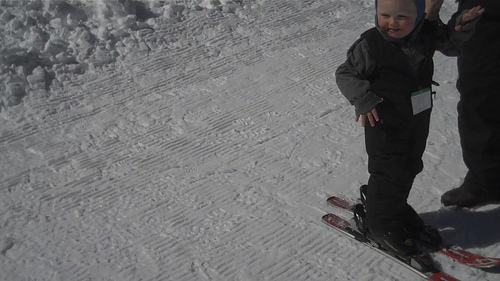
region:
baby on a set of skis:
[311, 171, 463, 272]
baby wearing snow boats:
[353, 189, 440, 264]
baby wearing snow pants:
[358, 107, 415, 232]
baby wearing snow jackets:
[298, 19, 452, 157]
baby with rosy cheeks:
[373, 15, 413, 37]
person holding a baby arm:
[425, 0, 476, 75]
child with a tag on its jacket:
[403, 83, 438, 118]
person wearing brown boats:
[429, 168, 492, 218]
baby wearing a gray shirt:
[328, 41, 374, 119]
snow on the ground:
[83, 56, 169, 194]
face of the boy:
[362, 3, 442, 49]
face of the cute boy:
[365, 4, 432, 59]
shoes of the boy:
[336, 169, 441, 256]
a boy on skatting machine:
[307, 158, 471, 279]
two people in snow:
[328, 59, 496, 200]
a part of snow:
[14, 3, 200, 56]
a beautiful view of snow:
[33, 35, 495, 253]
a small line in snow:
[284, 79, 356, 134]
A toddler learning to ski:
[320, 0, 499, 277]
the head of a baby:
[347, 0, 447, 62]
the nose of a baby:
[381, 18, 407, 48]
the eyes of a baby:
[371, 9, 424, 25]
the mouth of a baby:
[378, 21, 410, 44]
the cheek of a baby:
[368, 7, 395, 38]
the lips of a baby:
[373, 22, 414, 42]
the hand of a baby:
[346, 95, 390, 135]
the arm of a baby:
[331, 17, 386, 103]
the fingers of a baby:
[341, 94, 396, 152]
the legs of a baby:
[354, 99, 446, 234]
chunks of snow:
[4, 3, 111, 57]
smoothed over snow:
[21, 99, 305, 279]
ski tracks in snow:
[37, 112, 273, 279]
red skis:
[321, 186, 496, 277]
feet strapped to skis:
[315, 175, 496, 275]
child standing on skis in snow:
[333, 1, 498, 279]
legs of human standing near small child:
[425, 0, 499, 207]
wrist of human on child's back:
[425, 0, 446, 25]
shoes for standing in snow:
[441, 167, 499, 206]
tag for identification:
[408, 87, 435, 117]